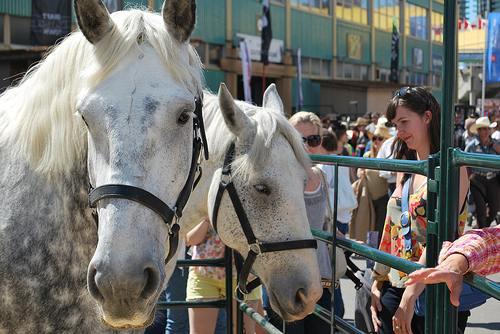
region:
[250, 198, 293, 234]
black dots on face of horse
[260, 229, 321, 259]
black horse bridle strap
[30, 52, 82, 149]
long white hair on head of horse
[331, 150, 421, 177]
green metal guard railing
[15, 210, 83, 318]
pattern on side of horse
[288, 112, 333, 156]
woman in dark sunglasses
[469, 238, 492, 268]
design on sleeve of shirt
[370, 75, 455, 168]
woman with long brown hair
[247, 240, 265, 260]
silver metal ring on horse bridle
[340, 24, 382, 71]
yellow sign hanging on building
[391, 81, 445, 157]
a woman with sunglasses on her head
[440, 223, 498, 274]
a pink and orange sleeve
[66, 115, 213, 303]
harness around a horses nose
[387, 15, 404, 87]
a black flag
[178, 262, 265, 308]
girl wearing yellow shorts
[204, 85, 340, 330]
a white horse with gray spots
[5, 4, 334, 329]
two horses standing outside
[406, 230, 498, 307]
an outreached hand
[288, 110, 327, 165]
blonde woman wearing sunglasses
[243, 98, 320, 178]
white hair on the horses head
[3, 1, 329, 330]
Two horses in the foreground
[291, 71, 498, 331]
A crowd of people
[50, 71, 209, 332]
Horse is looking at the camera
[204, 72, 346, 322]
A side view of a horse's head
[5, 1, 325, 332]
Horses are light gray in color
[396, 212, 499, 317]
A hand is reaching out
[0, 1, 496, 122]
A building is in the background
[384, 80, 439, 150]
Woman's sunglasses is on her head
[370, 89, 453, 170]
Woman's hair is dark brown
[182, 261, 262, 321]
Person is wearing yellow shorts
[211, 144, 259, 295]
the horse's bridle and reins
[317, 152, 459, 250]
the metal railing of the gate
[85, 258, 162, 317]
the grey nose area of the horse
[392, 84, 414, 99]
black sunglasses on the girls head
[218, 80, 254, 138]
the horses white ears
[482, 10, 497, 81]
a blue advertising banner flag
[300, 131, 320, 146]
the blond girl is wearing black sunglasses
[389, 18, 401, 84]
a flag on a pole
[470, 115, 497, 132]
a man wearing a cowboy hat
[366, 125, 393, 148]
a girl wearing a cowgirl hat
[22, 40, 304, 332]
two horses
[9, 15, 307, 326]
the horses in a pen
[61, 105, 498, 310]
the gate of the pen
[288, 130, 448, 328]
the gate is green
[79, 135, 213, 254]
the bridal on the horse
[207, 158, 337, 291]
the bridal of the horse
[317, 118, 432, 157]
a crowd of people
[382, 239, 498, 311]
the hand in the penn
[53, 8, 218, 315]
the head of the horse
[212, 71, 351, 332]
the head of the horse